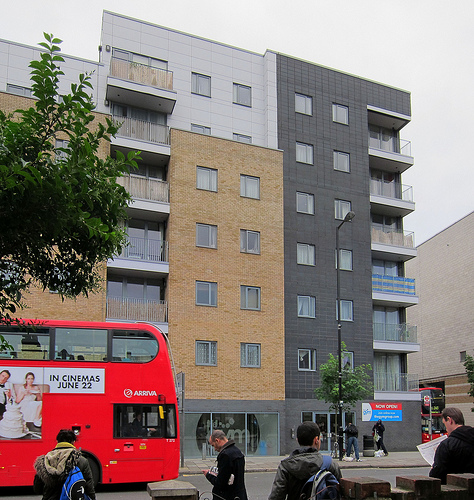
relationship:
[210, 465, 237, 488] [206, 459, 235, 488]
news paper on mans arm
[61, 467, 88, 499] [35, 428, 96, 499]
backpack hanging on mans shoulder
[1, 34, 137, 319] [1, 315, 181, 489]
trees next to bus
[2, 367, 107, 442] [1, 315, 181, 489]
advertisement on bus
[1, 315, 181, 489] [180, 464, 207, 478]
red bus parked at curb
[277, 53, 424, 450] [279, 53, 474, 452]
grey building at corner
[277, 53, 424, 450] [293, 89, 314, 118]
building has windows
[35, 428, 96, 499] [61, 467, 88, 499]
man with a backpack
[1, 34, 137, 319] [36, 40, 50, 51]
tree has green leaves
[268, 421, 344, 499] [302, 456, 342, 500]
man has a grey backpack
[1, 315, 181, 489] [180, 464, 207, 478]
red bus at curb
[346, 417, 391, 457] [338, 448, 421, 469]
pedestrians on walkway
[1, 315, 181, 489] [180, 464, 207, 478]
double decker at curb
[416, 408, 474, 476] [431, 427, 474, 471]
man reading with a black jacket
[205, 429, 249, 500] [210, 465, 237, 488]
man with a newspaper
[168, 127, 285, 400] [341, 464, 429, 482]
brown building across street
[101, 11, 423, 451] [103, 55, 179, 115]
building with balcony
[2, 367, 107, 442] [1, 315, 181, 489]
advertising on bus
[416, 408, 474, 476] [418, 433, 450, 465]
man reading a newspaper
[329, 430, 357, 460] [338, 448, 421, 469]
bicycle on walkway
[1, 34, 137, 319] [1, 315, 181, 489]
green tree above bus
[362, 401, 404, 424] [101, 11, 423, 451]
advertising on building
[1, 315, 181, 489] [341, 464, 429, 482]
bus on street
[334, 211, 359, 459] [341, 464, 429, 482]
street light across street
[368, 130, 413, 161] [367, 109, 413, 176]
railing on balcony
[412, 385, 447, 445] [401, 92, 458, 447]
bus driving around corner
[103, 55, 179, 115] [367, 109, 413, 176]
balcony attached to apartment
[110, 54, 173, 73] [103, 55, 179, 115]
railing attached to balcony